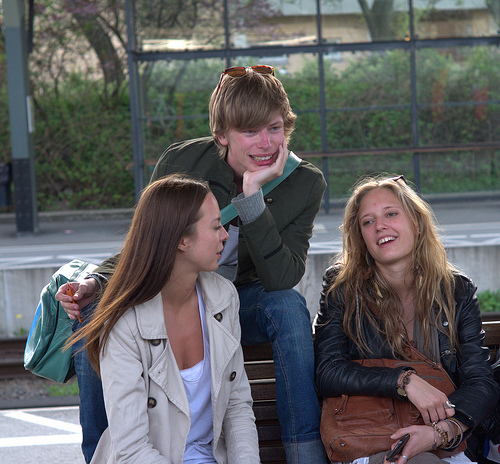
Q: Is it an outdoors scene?
A: Yes, it is outdoors.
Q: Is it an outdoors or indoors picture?
A: It is outdoors.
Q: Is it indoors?
A: No, it is outdoors.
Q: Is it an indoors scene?
A: No, it is outdoors.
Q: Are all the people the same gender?
A: No, they are both male and female.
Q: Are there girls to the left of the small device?
A: Yes, there is a girl to the left of the phone.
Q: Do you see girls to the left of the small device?
A: Yes, there is a girl to the left of the phone.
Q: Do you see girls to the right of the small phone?
A: No, the girl is to the left of the phone.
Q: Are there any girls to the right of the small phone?
A: No, the girl is to the left of the phone.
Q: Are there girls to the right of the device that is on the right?
A: No, the girl is to the left of the phone.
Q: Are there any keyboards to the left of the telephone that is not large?
A: No, there is a girl to the left of the phone.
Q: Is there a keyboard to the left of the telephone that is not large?
A: No, there is a girl to the left of the phone.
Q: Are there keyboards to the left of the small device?
A: No, there is a girl to the left of the phone.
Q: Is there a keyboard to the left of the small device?
A: No, there is a girl to the left of the phone.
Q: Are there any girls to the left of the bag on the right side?
A: Yes, there is a girl to the left of the bag.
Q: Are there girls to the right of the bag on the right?
A: No, the girl is to the left of the bag.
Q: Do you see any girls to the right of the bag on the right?
A: No, the girl is to the left of the bag.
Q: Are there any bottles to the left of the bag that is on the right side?
A: No, there is a girl to the left of the bag.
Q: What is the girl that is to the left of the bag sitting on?
A: The girl is sitting on the bench.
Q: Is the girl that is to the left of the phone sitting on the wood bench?
A: Yes, the girl is sitting on the bench.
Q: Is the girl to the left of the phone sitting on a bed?
A: No, the girl is sitting on the bench.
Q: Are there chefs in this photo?
A: No, there are no chefs.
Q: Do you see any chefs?
A: No, there are no chefs.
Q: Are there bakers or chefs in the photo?
A: No, there are no chefs or bakers.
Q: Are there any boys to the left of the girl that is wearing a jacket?
A: Yes, there is a boy to the left of the girl.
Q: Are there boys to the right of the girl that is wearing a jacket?
A: No, the boy is to the left of the girl.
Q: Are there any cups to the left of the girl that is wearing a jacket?
A: No, there is a boy to the left of the girl.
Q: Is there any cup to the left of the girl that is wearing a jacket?
A: No, there is a boy to the left of the girl.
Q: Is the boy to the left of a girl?
A: Yes, the boy is to the left of a girl.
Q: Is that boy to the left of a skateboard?
A: No, the boy is to the left of a girl.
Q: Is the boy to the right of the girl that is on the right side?
A: No, the boy is to the left of the girl.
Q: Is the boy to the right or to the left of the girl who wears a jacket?
A: The boy is to the left of the girl.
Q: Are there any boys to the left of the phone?
A: Yes, there is a boy to the left of the phone.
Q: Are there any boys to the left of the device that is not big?
A: Yes, there is a boy to the left of the phone.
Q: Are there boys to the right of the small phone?
A: No, the boy is to the left of the phone.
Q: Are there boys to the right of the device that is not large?
A: No, the boy is to the left of the phone.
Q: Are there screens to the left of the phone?
A: No, there is a boy to the left of the phone.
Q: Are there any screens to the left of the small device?
A: No, there is a boy to the left of the phone.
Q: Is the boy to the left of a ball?
A: No, the boy is to the left of the telephone.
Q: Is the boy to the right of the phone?
A: No, the boy is to the left of the phone.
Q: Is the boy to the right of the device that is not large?
A: No, the boy is to the left of the phone.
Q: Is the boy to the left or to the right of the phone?
A: The boy is to the left of the phone.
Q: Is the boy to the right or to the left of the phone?
A: The boy is to the left of the phone.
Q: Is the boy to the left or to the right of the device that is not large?
A: The boy is to the left of the phone.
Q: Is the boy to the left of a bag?
A: Yes, the boy is to the left of a bag.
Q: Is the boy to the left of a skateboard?
A: No, the boy is to the left of a bag.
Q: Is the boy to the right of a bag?
A: No, the boy is to the left of a bag.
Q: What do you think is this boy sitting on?
A: The boy is sitting on the bench.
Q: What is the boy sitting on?
A: The boy is sitting on the bench.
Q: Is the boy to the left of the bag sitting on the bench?
A: Yes, the boy is sitting on the bench.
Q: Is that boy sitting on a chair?
A: No, the boy is sitting on the bench.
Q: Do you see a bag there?
A: Yes, there is a bag.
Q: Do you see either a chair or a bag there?
A: Yes, there is a bag.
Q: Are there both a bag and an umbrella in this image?
A: No, there is a bag but no umbrellas.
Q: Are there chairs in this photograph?
A: No, there are no chairs.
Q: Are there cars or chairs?
A: No, there are no chairs or cars.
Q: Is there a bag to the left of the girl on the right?
A: Yes, there is a bag to the left of the girl.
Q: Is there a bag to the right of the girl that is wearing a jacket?
A: No, the bag is to the left of the girl.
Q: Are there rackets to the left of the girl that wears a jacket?
A: No, there is a bag to the left of the girl.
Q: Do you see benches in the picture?
A: Yes, there is a bench.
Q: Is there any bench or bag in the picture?
A: Yes, there is a bench.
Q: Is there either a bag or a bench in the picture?
A: Yes, there is a bench.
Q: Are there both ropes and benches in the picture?
A: No, there is a bench but no ropes.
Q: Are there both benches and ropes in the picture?
A: No, there is a bench but no ropes.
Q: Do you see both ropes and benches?
A: No, there is a bench but no ropes.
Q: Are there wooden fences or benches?
A: Yes, there is a wood bench.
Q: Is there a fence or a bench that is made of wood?
A: Yes, the bench is made of wood.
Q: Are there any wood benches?
A: Yes, there is a wood bench.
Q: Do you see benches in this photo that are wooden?
A: Yes, there is a bench that is wooden.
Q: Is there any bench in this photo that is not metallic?
A: Yes, there is a wooden bench.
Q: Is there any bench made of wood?
A: Yes, there is a bench that is made of wood.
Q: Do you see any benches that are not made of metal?
A: Yes, there is a bench that is made of wood.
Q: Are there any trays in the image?
A: No, there are no trays.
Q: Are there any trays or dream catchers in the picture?
A: No, there are no trays or dream catchers.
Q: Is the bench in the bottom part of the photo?
A: Yes, the bench is in the bottom of the image.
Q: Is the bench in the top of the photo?
A: No, the bench is in the bottom of the image.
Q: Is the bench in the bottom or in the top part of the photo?
A: The bench is in the bottom of the image.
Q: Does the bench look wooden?
A: Yes, the bench is wooden.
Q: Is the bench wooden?
A: Yes, the bench is wooden.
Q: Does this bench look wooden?
A: Yes, the bench is wooden.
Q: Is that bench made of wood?
A: Yes, the bench is made of wood.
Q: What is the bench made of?
A: The bench is made of wood.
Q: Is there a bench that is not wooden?
A: No, there is a bench but it is wooden.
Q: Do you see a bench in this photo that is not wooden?
A: No, there is a bench but it is wooden.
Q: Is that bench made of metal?
A: No, the bench is made of wood.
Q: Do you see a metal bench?
A: No, there is a bench but it is made of wood.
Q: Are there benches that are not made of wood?
A: No, there is a bench but it is made of wood.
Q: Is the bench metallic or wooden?
A: The bench is wooden.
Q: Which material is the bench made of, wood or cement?
A: The bench is made of wood.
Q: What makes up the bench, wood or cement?
A: The bench is made of wood.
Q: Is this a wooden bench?
A: Yes, this is a wooden bench.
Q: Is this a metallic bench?
A: No, this is a wooden bench.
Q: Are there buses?
A: No, there are no buses.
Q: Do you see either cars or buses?
A: No, there are no buses or cars.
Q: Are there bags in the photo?
A: Yes, there is a bag.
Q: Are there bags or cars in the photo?
A: Yes, there is a bag.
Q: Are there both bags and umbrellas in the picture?
A: No, there is a bag but no umbrellas.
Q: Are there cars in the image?
A: No, there are no cars.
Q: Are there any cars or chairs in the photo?
A: No, there are no cars or chairs.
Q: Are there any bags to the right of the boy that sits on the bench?
A: Yes, there is a bag to the right of the boy.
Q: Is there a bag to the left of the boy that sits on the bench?
A: No, the bag is to the right of the boy.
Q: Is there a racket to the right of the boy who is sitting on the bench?
A: No, there is a bag to the right of the boy.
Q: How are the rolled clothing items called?
A: The clothing items are jeans.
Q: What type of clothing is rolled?
A: The clothing is jeans.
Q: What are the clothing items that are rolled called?
A: The clothing items are jeans.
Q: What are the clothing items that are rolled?
A: The clothing items are jeans.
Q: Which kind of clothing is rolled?
A: The clothing is jeans.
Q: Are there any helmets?
A: No, there are no helmets.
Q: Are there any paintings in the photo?
A: No, there are no paintings.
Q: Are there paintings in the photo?
A: No, there are no paintings.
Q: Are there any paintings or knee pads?
A: No, there are no paintings or knee pads.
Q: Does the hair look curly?
A: Yes, the hair is curly.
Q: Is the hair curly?
A: Yes, the hair is curly.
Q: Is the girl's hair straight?
A: No, the hair is curly.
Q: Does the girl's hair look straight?
A: No, the hair is curly.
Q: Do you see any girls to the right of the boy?
A: Yes, there is a girl to the right of the boy.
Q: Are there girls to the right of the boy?
A: Yes, there is a girl to the right of the boy.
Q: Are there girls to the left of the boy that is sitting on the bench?
A: No, the girl is to the right of the boy.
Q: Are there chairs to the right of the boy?
A: No, there is a girl to the right of the boy.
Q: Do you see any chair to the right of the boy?
A: No, there is a girl to the right of the boy.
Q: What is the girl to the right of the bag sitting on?
A: The girl is sitting on the bench.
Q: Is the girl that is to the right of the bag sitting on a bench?
A: Yes, the girl is sitting on a bench.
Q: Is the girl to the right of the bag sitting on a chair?
A: No, the girl is sitting on a bench.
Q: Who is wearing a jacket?
A: The girl is wearing a jacket.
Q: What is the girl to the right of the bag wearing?
A: The girl is wearing a jacket.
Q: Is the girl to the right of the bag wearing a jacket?
A: Yes, the girl is wearing a jacket.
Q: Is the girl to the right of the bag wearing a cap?
A: No, the girl is wearing a jacket.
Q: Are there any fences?
A: Yes, there is a fence.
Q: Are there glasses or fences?
A: Yes, there is a fence.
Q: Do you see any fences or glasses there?
A: Yes, there is a fence.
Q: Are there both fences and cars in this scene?
A: No, there is a fence but no cars.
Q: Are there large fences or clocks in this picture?
A: Yes, there is a large fence.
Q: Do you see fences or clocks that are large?
A: Yes, the fence is large.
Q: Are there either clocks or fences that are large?
A: Yes, the fence is large.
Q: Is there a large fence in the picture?
A: Yes, there is a large fence.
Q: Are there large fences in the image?
A: Yes, there is a large fence.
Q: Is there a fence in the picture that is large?
A: Yes, there is a fence that is large.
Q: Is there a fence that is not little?
A: Yes, there is a large fence.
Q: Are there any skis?
A: No, there are no skis.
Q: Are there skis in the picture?
A: No, there are no skis.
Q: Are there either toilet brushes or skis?
A: No, there are no skis or toilet brushes.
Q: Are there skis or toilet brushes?
A: No, there are no skis or toilet brushes.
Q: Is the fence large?
A: Yes, the fence is large.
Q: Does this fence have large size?
A: Yes, the fence is large.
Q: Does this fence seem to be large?
A: Yes, the fence is large.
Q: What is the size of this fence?
A: The fence is large.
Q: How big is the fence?
A: The fence is large.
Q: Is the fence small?
A: No, the fence is large.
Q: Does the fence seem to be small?
A: No, the fence is large.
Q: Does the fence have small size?
A: No, the fence is large.